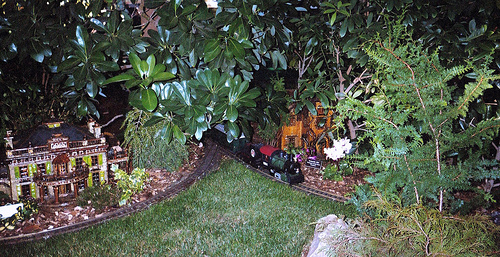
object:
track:
[296, 183, 349, 202]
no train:
[270, 104, 330, 163]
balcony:
[28, 149, 133, 207]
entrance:
[37, 182, 109, 210]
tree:
[200, 3, 495, 99]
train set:
[218, 100, 338, 178]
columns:
[20, 180, 108, 201]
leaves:
[132, 53, 164, 103]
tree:
[12, 4, 249, 169]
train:
[224, 114, 334, 205]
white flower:
[322, 135, 356, 164]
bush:
[338, 33, 498, 208]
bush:
[113, 0, 250, 133]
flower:
[322, 134, 356, 166]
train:
[230, 126, 280, 176]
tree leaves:
[352, 39, 498, 244]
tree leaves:
[14, 0, 264, 129]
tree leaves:
[267, 6, 367, 101]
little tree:
[339, 47, 469, 215]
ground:
[93, 196, 371, 228]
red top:
[253, 139, 279, 157]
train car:
[247, 139, 298, 182]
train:
[253, 104, 341, 207]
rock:
[296, 211, 371, 255]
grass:
[70, 227, 297, 255]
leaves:
[130, 41, 229, 86]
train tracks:
[106, 205, 148, 216]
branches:
[54, 32, 434, 147]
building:
[2, 110, 132, 202]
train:
[259, 141, 308, 183]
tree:
[9, 2, 266, 138]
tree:
[353, 50, 490, 180]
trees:
[11, 3, 497, 193]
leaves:
[1, 4, 489, 54]